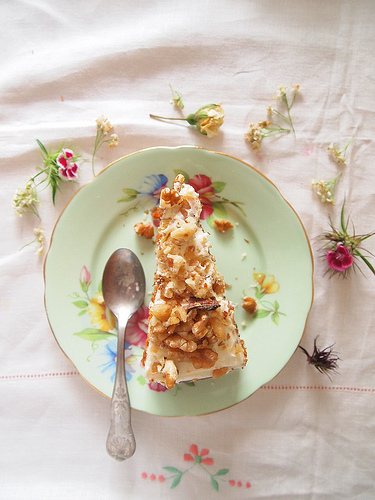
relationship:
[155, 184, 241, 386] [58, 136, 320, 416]
pastry on dish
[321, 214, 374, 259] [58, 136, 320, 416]
flower beside dish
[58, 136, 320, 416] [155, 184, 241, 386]
dish with pastry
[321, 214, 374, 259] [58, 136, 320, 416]
flower near dish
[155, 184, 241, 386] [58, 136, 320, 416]
pastry on top of dish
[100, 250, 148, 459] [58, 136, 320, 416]
spoon above dish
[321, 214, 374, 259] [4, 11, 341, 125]
flower on tablecloth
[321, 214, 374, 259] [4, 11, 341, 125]
flower on top tablecloth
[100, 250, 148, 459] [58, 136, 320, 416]
spoon on dish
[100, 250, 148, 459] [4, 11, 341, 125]
spoon on tablecloth